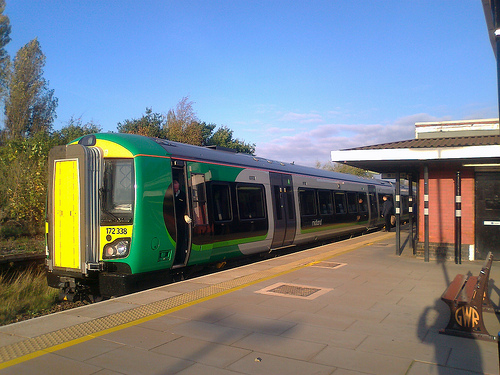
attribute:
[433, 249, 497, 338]
park bench — wooden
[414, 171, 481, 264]
wall — red, bricked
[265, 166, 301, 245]
door — grey